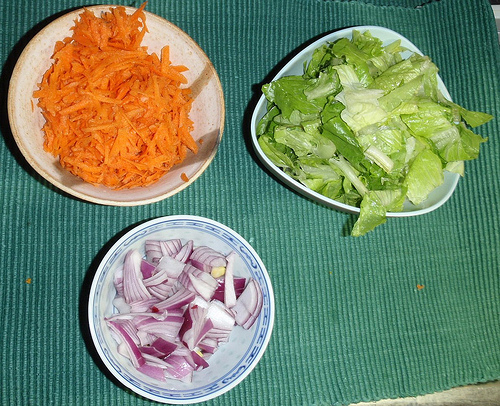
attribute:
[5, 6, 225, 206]
plate — white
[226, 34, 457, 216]
lettuce — chopped, mixed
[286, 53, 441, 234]
lettuce — torn, leaves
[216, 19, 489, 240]
bowl — white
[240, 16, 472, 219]
plate — white, ful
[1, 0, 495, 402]
cloth — green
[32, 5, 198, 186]
carrots — shredded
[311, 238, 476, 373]
cloth — green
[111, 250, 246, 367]
onions — red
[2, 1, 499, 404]
placemat — green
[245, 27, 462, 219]
plate — white, triangular, rounded 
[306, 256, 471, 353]
tablecloth —  turquoise, woven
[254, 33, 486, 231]
lettuce — chopped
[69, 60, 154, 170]
vegetables — orange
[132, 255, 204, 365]
onions — chopped, red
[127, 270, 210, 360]
onions — red, chopped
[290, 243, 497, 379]
placemat — green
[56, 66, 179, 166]
carrots — shredded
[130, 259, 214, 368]
onions — red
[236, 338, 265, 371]
trim — blue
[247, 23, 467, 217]
bowl — small, white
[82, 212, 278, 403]
bowl — white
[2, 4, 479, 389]
tablecloth — blue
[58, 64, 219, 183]
pattern — brown